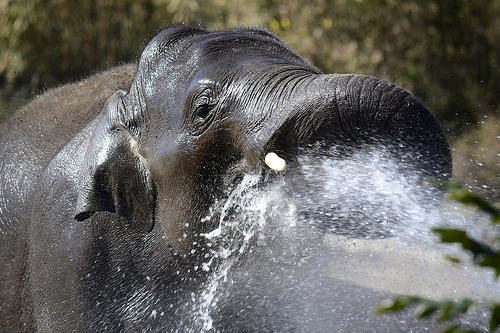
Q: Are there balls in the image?
A: No, there are no balls.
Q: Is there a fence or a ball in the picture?
A: No, there are no balls or fences.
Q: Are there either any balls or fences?
A: No, there are no balls or fences.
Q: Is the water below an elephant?
A: Yes, the water is below an elephant.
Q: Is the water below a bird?
A: No, the water is below an elephant.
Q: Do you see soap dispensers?
A: No, there are no soap dispensers.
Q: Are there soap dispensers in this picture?
A: No, there are no soap dispensers.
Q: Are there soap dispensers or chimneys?
A: No, there are no soap dispensers or chimneys.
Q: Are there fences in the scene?
A: No, there are no fences.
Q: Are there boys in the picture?
A: No, there are no boys.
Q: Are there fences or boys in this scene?
A: No, there are no boys or fences.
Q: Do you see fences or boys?
A: No, there are no boys or fences.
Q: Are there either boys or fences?
A: No, there are no boys or fences.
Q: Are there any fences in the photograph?
A: No, there are no fences.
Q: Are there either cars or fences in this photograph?
A: No, there are no fences or cars.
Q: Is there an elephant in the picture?
A: Yes, there is an elephant.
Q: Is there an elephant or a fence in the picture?
A: Yes, there is an elephant.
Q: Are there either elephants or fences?
A: Yes, there is an elephant.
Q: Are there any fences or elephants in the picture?
A: Yes, there is an elephant.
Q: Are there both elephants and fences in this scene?
A: No, there is an elephant but no fences.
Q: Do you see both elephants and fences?
A: No, there is an elephant but no fences.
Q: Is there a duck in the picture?
A: No, there are no ducks.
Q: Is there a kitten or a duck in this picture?
A: No, there are no ducks or kittens.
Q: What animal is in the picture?
A: The animal is an elephant.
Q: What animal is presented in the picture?
A: The animal is an elephant.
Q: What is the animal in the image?
A: The animal is an elephant.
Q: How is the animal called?
A: The animal is an elephant.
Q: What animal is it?
A: The animal is an elephant.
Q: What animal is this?
A: This is an elephant.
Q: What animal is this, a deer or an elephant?
A: This is an elephant.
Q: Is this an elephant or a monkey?
A: This is an elephant.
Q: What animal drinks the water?
A: The elephant drinks the water.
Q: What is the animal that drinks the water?
A: The animal is an elephant.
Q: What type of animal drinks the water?
A: The animal is an elephant.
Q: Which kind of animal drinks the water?
A: The animal is an elephant.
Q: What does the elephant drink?
A: The elephant drinks water.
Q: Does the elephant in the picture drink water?
A: Yes, the elephant drinks water.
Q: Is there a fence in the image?
A: No, there are no fences.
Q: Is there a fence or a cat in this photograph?
A: No, there are no fences or cats.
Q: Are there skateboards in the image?
A: No, there are no skateboards.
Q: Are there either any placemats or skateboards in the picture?
A: No, there are no skateboards or placemats.